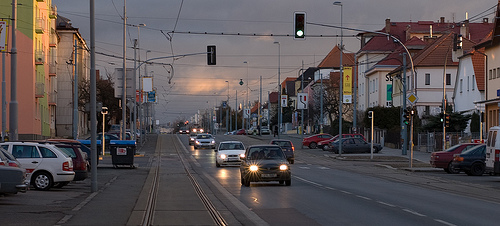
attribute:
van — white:
[476, 124, 497, 170]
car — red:
[243, 148, 295, 181]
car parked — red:
[432, 136, 478, 169]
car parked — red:
[301, 123, 351, 148]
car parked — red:
[37, 131, 92, 179]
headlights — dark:
[247, 161, 288, 173]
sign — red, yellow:
[341, 64, 354, 102]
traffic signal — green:
[293, 13, 305, 35]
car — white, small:
[213, 140, 246, 167]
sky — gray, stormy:
[19, 5, 451, 121]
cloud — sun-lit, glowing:
[149, 57, 326, 119]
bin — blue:
[103, 131, 143, 176]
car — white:
[0, 136, 75, 190]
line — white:
[356, 193, 369, 201]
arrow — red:
[345, 72, 350, 82]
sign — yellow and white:
[342, 63, 354, 106]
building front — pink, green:
[4, 8, 62, 149]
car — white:
[213, 140, 244, 164]